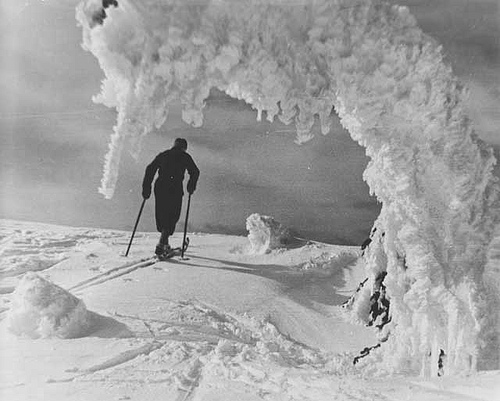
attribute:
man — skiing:
[142, 137, 202, 264]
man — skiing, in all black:
[140, 139, 194, 254]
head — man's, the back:
[165, 131, 193, 154]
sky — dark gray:
[204, 140, 353, 206]